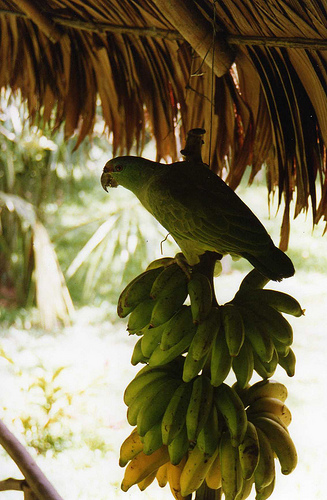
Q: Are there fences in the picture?
A: No, there are no fences.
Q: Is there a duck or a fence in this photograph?
A: No, there are no fences or ducks.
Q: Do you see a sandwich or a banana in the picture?
A: Yes, there are bananas.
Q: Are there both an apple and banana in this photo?
A: No, there are bananas but no apples.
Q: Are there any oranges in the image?
A: No, there are no oranges.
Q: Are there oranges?
A: No, there are no oranges.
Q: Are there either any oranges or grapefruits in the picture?
A: No, there are no oranges or grapefruits.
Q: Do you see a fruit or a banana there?
A: Yes, there is a banana.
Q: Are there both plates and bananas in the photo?
A: No, there is a banana but no plates.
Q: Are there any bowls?
A: No, there are no bowls.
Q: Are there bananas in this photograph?
A: Yes, there is a banana.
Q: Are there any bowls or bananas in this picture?
A: Yes, there is a banana.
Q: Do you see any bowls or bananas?
A: Yes, there is a banana.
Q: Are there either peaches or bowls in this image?
A: No, there are no bowls or peaches.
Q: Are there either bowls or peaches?
A: No, there are no bowls or peaches.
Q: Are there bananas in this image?
A: Yes, there are bananas.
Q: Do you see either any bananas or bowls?
A: Yes, there are bananas.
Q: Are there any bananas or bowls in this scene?
A: Yes, there are bananas.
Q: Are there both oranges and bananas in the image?
A: No, there are bananas but no oranges.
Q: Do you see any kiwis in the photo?
A: No, there are no kiwis.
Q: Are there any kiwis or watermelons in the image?
A: No, there are no kiwis or watermelons.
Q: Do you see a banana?
A: Yes, there is a banana.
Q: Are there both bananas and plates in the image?
A: No, there is a banana but no plates.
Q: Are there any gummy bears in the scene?
A: No, there are no gummy bears.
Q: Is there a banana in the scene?
A: Yes, there is a banana.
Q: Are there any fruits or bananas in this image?
A: Yes, there is a banana.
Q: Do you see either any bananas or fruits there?
A: Yes, there is a banana.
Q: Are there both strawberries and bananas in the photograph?
A: No, there is a banana but no strawberries.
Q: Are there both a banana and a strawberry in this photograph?
A: No, there is a banana but no strawberries.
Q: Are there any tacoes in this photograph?
A: No, there are no tacoes.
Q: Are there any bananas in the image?
A: Yes, there is a banana.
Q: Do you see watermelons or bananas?
A: Yes, there is a banana.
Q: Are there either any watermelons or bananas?
A: Yes, there is a banana.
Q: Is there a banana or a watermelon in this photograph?
A: Yes, there is a banana.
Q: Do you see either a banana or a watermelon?
A: Yes, there is a banana.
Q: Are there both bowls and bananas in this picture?
A: No, there is a banana but no bowls.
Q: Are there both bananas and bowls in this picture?
A: No, there is a banana but no bowls.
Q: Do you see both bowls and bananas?
A: No, there is a banana but no bowls.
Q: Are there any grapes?
A: No, there are no grapes.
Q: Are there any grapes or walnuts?
A: No, there are no grapes or walnuts.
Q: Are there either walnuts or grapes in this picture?
A: No, there are no grapes or walnuts.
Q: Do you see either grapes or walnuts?
A: No, there are no grapes or walnuts.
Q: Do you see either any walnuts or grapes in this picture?
A: No, there are no grapes or walnuts.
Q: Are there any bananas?
A: Yes, there is a banana.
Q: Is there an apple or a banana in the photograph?
A: Yes, there is a banana.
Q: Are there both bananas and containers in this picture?
A: No, there is a banana but no containers.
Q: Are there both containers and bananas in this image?
A: No, there is a banana but no containers.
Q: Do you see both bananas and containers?
A: No, there is a banana but no containers.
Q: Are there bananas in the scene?
A: Yes, there is a banana.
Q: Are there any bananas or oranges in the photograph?
A: Yes, there is a banana.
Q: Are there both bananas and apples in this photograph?
A: No, there is a banana but no apples.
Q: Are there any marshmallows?
A: No, there are no marshmallows.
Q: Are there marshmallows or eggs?
A: No, there are no marshmallows or eggs.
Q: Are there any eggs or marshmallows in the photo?
A: No, there are no marshmallows or eggs.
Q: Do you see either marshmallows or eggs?
A: No, there are no marshmallows or eggs.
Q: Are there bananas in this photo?
A: Yes, there are bananas.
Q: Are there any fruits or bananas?
A: Yes, there are bananas.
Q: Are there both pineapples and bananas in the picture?
A: No, there are bananas but no pineapples.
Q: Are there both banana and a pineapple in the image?
A: No, there are bananas but no pineapples.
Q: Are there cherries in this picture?
A: No, there are no cherries.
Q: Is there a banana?
A: Yes, there is a banana.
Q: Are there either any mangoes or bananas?
A: Yes, there is a banana.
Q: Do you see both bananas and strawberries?
A: No, there is a banana but no strawberries.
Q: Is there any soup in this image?
A: No, there is no soup.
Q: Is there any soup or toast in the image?
A: No, there are no soup or toasts.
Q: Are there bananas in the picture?
A: Yes, there is a banana.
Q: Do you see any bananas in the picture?
A: Yes, there is a banana.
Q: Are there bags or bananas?
A: Yes, there is a banana.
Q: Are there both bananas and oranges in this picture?
A: No, there is a banana but no oranges.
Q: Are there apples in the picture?
A: No, there are no apples.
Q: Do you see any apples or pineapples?
A: No, there are no apples or pineapples.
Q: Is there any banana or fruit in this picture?
A: Yes, there is a banana.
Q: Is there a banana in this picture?
A: Yes, there is a banana.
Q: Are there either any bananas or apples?
A: Yes, there is a banana.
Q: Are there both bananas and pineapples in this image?
A: No, there is a banana but no pineapples.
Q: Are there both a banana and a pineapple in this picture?
A: No, there is a banana but no pineapples.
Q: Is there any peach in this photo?
A: No, there are no peaches.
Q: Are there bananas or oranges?
A: Yes, there is a banana.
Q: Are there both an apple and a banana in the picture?
A: No, there is a banana but no apples.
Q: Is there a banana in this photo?
A: Yes, there is a banana.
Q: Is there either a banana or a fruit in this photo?
A: Yes, there is a banana.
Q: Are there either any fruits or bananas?
A: Yes, there is a banana.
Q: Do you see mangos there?
A: No, there are no mangos.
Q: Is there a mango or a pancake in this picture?
A: No, there are no mangoes or pancakes.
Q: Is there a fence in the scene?
A: No, there are no fences.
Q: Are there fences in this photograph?
A: No, there are no fences.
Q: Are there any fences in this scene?
A: No, there are no fences.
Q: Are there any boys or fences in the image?
A: No, there are no fences or boys.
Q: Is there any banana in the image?
A: Yes, there is a banana.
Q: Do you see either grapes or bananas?
A: Yes, there is a banana.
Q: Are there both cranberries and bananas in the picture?
A: No, there is a banana but no cranberries.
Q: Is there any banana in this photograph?
A: Yes, there is a banana.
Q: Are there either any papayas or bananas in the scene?
A: Yes, there is a banana.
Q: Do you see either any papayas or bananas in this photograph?
A: Yes, there is a banana.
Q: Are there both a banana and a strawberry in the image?
A: No, there is a banana but no strawberries.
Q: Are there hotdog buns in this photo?
A: No, there are no hotdog buns.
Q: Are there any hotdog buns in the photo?
A: No, there are no hotdog buns.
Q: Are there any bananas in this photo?
A: Yes, there are bananas.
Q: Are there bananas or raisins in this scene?
A: Yes, there are bananas.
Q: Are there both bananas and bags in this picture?
A: No, there are bananas but no bags.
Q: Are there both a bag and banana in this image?
A: No, there are bananas but no bags.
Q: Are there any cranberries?
A: No, there are no cranberries.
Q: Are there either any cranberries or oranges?
A: No, there are no cranberries or oranges.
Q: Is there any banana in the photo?
A: Yes, there are bananas.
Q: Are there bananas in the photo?
A: Yes, there are bananas.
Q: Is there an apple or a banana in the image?
A: Yes, there are bananas.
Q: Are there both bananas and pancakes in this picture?
A: No, there are bananas but no pancakes.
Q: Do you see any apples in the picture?
A: No, there are no apples.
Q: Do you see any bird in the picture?
A: Yes, there is a bird.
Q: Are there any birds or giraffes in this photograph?
A: Yes, there is a bird.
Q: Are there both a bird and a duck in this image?
A: No, there is a bird but no ducks.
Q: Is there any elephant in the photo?
A: No, there are no elephants.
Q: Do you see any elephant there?
A: No, there are no elephants.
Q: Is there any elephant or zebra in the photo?
A: No, there are no elephants or zebras.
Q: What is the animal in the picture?
A: The animal is a bird.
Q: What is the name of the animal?
A: The animal is a bird.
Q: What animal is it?
A: The animal is a bird.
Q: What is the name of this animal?
A: This is a bird.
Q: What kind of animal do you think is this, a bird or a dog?
A: This is a bird.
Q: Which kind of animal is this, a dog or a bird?
A: This is a bird.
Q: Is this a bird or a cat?
A: This is a bird.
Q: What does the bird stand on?
A: The bird stands on the banana.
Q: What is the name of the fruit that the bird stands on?
A: The fruit is a banana.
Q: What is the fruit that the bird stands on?
A: The fruit is a banana.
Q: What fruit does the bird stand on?
A: The bird stands on the banana.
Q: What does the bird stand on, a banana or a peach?
A: The bird stands on a banana.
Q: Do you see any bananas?
A: Yes, there is a banana.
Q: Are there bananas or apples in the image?
A: Yes, there is a banana.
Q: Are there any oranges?
A: No, there are no oranges.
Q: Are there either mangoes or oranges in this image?
A: No, there are no oranges or mangoes.